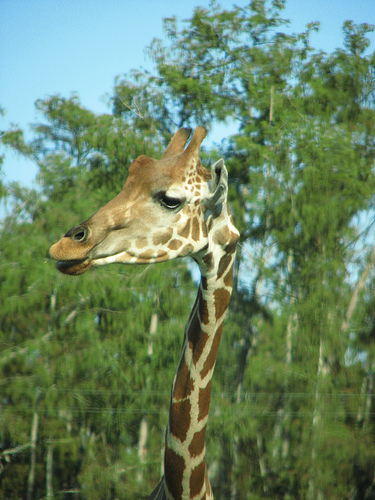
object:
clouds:
[0, 0, 374, 314]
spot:
[166, 236, 183, 251]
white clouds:
[16, 28, 50, 56]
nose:
[61, 222, 88, 243]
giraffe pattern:
[150, 222, 175, 248]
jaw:
[90, 250, 190, 268]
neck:
[162, 249, 236, 499]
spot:
[162, 443, 185, 498]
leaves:
[324, 419, 342, 446]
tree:
[1, 0, 374, 498]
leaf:
[337, 105, 349, 123]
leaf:
[306, 165, 319, 177]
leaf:
[297, 90, 305, 104]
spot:
[194, 379, 213, 424]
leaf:
[23, 351, 35, 364]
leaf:
[119, 303, 131, 321]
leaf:
[119, 342, 131, 354]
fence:
[0, 387, 372, 413]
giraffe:
[44, 123, 240, 499]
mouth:
[48, 245, 92, 277]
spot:
[152, 249, 168, 265]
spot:
[187, 421, 208, 459]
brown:
[199, 384, 212, 420]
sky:
[0, 0, 374, 318]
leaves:
[273, 361, 287, 388]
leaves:
[79, 348, 90, 364]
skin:
[189, 337, 206, 444]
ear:
[206, 156, 230, 215]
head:
[46, 121, 241, 282]